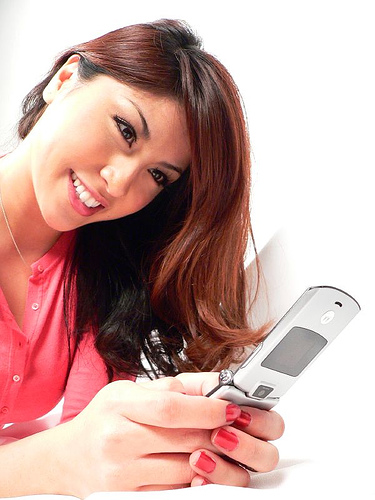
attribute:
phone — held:
[203, 279, 362, 412]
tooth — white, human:
[77, 188, 93, 205]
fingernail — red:
[199, 394, 256, 434]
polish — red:
[195, 452, 216, 473]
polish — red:
[211, 429, 239, 450]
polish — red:
[222, 405, 240, 420]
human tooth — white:
[71, 173, 76, 179]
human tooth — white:
[73, 178, 79, 186]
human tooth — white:
[75, 184, 84, 192]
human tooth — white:
[77, 191, 89, 202]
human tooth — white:
[84, 197, 95, 207]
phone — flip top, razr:
[167, 269, 365, 409]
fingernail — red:
[224, 397, 261, 439]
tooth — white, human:
[71, 176, 77, 186]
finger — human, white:
[119, 372, 249, 431]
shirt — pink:
[7, 233, 134, 438]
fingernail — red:
[212, 428, 238, 455]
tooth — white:
[83, 196, 93, 209]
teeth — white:
[84, 197, 95, 208]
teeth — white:
[78, 189, 91, 204]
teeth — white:
[75, 184, 87, 195]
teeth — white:
[72, 178, 80, 189]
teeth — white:
[70, 168, 76, 180]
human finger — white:
[124, 380, 239, 421]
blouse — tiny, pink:
[1, 221, 143, 438]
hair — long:
[17, 22, 278, 377]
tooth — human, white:
[74, 182, 84, 192]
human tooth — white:
[79, 184, 95, 202]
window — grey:
[260, 328, 328, 376]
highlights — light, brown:
[201, 78, 240, 305]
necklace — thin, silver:
[0, 192, 30, 274]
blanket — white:
[0, 404, 364, 497]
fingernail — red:
[225, 401, 242, 425]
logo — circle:
[318, 307, 335, 326]